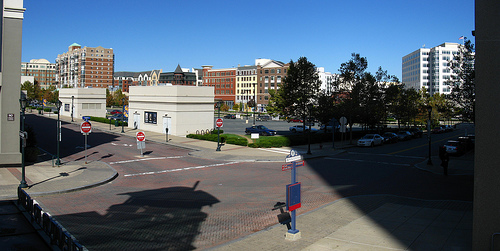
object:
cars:
[355, 133, 386, 147]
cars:
[440, 140, 467, 154]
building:
[55, 41, 114, 88]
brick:
[62, 196, 67, 199]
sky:
[21, 0, 475, 82]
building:
[126, 84, 213, 134]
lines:
[124, 161, 236, 177]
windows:
[421, 63, 426, 68]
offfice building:
[402, 41, 475, 117]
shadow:
[275, 125, 472, 251]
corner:
[15, 159, 120, 194]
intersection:
[0, 180, 221, 251]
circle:
[80, 121, 92, 133]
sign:
[282, 160, 307, 171]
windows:
[213, 72, 218, 76]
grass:
[183, 129, 288, 147]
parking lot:
[210, 116, 385, 147]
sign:
[287, 150, 299, 157]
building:
[0, 0, 23, 165]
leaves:
[283, 86, 291, 91]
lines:
[109, 155, 182, 166]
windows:
[456, 50, 461, 55]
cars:
[244, 124, 277, 136]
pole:
[286, 161, 298, 232]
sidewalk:
[203, 195, 500, 250]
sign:
[134, 131, 148, 141]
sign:
[80, 121, 94, 135]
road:
[0, 110, 476, 251]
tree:
[264, 56, 324, 132]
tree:
[330, 51, 380, 145]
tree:
[385, 86, 418, 132]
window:
[442, 51, 444, 54]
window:
[423, 63, 431, 68]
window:
[441, 89, 445, 92]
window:
[421, 56, 426, 61]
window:
[411, 70, 416, 72]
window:
[434, 81, 439, 85]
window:
[276, 76, 282, 81]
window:
[276, 82, 283, 88]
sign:
[215, 118, 226, 129]